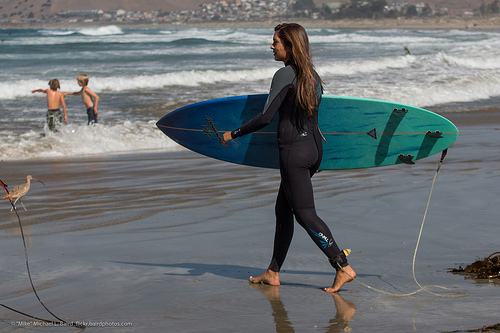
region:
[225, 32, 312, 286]
A woman is visible.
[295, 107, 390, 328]
A woman is visible.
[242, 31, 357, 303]
A woman is visible.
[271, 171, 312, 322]
A woman is visible.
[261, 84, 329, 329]
A woman is visible.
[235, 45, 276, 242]
A woman is visible.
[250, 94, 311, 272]
A woman is visible.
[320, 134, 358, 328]
A woman is visible.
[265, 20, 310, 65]
the head of a woman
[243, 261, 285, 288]
the foot of a woman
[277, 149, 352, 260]
the leg of a woman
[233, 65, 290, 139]
the arm of a woman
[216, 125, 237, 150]
the hand of a woman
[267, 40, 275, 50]
the nose of a woman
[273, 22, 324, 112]
the brown hair of a woman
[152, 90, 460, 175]
a blue and green surfboard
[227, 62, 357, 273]
a black and gray wet suit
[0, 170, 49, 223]
a bird on the beach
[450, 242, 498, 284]
pile of seaweed on beach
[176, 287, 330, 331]
wet sand on beach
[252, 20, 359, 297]
woman in black and grey wet suit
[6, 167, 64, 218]
bird walking down beach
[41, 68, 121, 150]
two boys playing in water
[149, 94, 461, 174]
blue and green surf board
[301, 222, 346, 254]
design on black wetsuit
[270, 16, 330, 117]
woman with long brown hair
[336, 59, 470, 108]
waves with white foam on top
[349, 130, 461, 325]
safety tether on surfboard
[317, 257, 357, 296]
the foot of a woman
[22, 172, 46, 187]
the head of a bird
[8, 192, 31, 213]
the legs of a bird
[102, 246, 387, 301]
a shadow on the ground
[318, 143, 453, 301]
surfboard safety strap in place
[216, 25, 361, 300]
surfer in wet suit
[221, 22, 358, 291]
woman in wet suit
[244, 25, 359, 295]
girl in a wet suit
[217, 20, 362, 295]
barefooted girl in black and gray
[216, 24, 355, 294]
girl in black and gray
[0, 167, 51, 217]
bird at the beach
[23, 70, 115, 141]
two boys in the surf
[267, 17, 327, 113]
long hair of a girl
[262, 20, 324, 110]
girl with brown hair